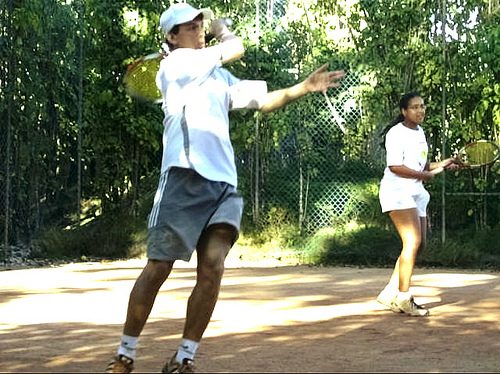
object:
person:
[105, 3, 348, 373]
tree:
[0, 2, 99, 254]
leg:
[177, 225, 238, 358]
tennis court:
[0, 2, 497, 373]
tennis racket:
[122, 20, 234, 104]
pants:
[147, 166, 244, 262]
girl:
[376, 90, 465, 316]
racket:
[427, 138, 498, 176]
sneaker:
[391, 295, 430, 316]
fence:
[0, 0, 500, 245]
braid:
[378, 113, 405, 136]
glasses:
[407, 106, 427, 111]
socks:
[174, 338, 198, 365]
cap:
[158, 3, 212, 38]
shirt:
[156, 47, 268, 185]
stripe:
[147, 167, 173, 228]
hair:
[377, 92, 423, 137]